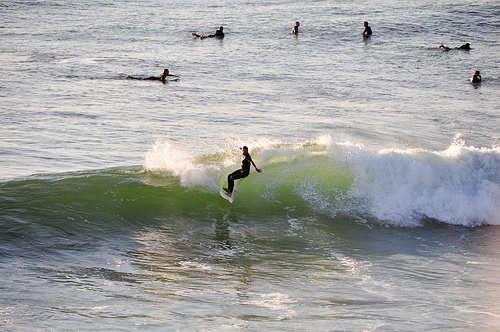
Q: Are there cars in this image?
A: No, there are no cars.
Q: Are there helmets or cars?
A: No, there are no cars or helmets.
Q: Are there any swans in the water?
A: No, there is a person in the water.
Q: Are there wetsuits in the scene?
A: Yes, there is a wetsuit.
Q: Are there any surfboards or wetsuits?
A: Yes, there is a wetsuit.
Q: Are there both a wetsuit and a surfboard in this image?
A: Yes, there are both a wetsuit and a surfboard.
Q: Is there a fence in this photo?
A: No, there are no fences.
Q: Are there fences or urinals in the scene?
A: No, there are no fences or urinals.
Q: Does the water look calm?
A: Yes, the water is calm.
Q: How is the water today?
A: The water is calm.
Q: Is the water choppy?
A: No, the water is calm.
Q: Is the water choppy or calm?
A: The water is calm.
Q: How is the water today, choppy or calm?
A: The water is calm.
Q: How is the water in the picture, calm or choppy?
A: The water is calm.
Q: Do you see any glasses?
A: No, there are no glasses.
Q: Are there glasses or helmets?
A: No, there are no glasses or helmets.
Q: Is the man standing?
A: Yes, the man is standing.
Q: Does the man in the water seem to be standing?
A: Yes, the man is standing.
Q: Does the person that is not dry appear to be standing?
A: Yes, the man is standing.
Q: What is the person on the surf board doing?
A: The man is standing.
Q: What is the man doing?
A: The man is standing.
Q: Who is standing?
A: The man is standing.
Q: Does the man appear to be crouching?
A: No, the man is standing.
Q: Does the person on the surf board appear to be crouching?
A: No, the man is standing.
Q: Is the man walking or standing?
A: The man is standing.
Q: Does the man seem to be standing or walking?
A: The man is standing.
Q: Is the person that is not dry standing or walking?
A: The man is standing.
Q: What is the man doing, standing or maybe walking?
A: The man is standing.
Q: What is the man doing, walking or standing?
A: The man is standing.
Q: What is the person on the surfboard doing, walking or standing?
A: The man is standing.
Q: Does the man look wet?
A: Yes, the man is wet.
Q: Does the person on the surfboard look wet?
A: Yes, the man is wet.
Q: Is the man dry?
A: No, the man is wet.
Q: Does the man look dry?
A: No, the man is wet.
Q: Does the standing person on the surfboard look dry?
A: No, the man is wet.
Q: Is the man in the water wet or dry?
A: The man is wet.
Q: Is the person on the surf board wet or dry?
A: The man is wet.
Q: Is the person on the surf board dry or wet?
A: The man is wet.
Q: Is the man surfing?
A: Yes, the man is surfing.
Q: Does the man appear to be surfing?
A: Yes, the man is surfing.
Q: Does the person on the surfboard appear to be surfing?
A: Yes, the man is surfing.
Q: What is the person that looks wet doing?
A: The man is surfing.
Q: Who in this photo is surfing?
A: The man is surfing.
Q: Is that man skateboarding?
A: No, the man is surfing.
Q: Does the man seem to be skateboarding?
A: No, the man is surfing.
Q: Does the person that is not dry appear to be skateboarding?
A: No, the man is surfing.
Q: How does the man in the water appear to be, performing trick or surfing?
A: The man is surfing.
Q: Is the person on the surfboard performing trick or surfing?
A: The man is surfing.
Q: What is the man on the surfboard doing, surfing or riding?
A: The man is surfing.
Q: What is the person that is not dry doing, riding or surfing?
A: The man is surfing.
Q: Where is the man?
A: The man is in the water.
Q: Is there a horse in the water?
A: No, there is a man in the water.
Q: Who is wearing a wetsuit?
A: The man is wearing a wetsuit.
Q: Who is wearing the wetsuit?
A: The man is wearing a wetsuit.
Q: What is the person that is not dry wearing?
A: The man is wearing a wetsuit.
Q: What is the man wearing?
A: The man is wearing a wetsuit.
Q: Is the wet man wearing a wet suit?
A: Yes, the man is wearing a wet suit.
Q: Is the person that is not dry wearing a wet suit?
A: Yes, the man is wearing a wet suit.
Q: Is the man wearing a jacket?
A: No, the man is wearing a wet suit.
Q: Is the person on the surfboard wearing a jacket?
A: No, the man is wearing a wet suit.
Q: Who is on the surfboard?
A: The man is on the surf board.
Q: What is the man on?
A: The man is on the surf board.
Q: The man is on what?
A: The man is on the surf board.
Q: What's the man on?
A: The man is on the surf board.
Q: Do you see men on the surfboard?
A: Yes, there is a man on the surfboard.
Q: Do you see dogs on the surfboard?
A: No, there is a man on the surfboard.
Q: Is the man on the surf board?
A: Yes, the man is on the surf board.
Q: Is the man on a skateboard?
A: No, the man is on the surf board.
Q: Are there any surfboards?
A: Yes, there is a surfboard.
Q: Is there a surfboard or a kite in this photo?
A: Yes, there is a surfboard.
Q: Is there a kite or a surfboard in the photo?
A: Yes, there is a surfboard.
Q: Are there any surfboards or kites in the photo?
A: Yes, there is a surfboard.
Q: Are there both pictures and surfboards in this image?
A: No, there is a surfboard but no pictures.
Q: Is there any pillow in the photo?
A: No, there are no pillows.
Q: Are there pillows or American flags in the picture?
A: No, there are no pillows or American flags.